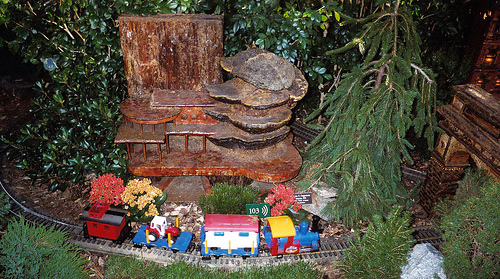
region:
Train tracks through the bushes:
[18, 170, 441, 270]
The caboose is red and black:
[68, 191, 133, 249]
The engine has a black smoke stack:
[258, 211, 340, 267]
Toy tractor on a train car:
[129, 208, 206, 261]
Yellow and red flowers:
[85, 163, 157, 212]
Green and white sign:
[233, 192, 286, 225]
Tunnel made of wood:
[373, 98, 494, 235]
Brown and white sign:
[271, 181, 322, 214]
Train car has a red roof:
[200, 212, 270, 256]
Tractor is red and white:
[143, 215, 185, 246]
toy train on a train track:
[13, 200, 343, 271]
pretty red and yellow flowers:
[86, 171, 166, 216]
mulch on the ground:
[28, 176, 83, 218]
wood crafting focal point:
[112, 12, 309, 197]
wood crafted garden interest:
[54, 3, 335, 204]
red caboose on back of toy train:
[78, 200, 136, 248]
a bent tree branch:
[322, 1, 439, 227]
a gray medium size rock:
[397, 241, 452, 277]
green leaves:
[225, 1, 351, 49]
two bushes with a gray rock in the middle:
[351, 182, 498, 277]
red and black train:
[86, 206, 129, 243]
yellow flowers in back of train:
[127, 180, 157, 213]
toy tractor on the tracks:
[142, 216, 189, 250]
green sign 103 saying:
[246, 203, 272, 216]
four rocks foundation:
[214, 47, 297, 155]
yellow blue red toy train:
[262, 215, 322, 252]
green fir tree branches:
[334, 12, 439, 216]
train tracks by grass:
[7, 195, 70, 238]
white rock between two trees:
[393, 230, 440, 277]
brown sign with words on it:
[287, 189, 317, 201]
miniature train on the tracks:
[64, 190, 366, 265]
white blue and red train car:
[180, 208, 279, 273]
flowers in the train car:
[72, 160, 181, 215]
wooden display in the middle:
[209, 38, 329, 196]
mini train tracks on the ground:
[28, 195, 79, 270]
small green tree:
[325, 195, 429, 276]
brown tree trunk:
[117, 15, 238, 150]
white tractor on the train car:
[142, 200, 212, 262]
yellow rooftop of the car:
[255, 210, 304, 247]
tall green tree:
[302, 0, 464, 236]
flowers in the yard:
[95, 167, 297, 213]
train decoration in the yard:
[82, 212, 340, 264]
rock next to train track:
[376, 243, 465, 274]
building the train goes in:
[438, 55, 498, 251]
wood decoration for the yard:
[104, 27, 313, 215]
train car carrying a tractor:
[134, 207, 173, 241]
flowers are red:
[80, 165, 315, 211]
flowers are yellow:
[119, 186, 180, 221]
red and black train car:
[73, 209, 130, 243]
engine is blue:
[265, 219, 342, 251]